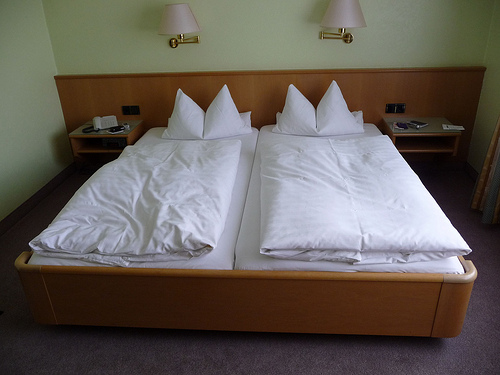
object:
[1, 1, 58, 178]
wall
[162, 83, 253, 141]
pillow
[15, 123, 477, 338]
bed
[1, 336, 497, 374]
carpet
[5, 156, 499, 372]
floor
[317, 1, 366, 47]
lights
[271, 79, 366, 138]
pillows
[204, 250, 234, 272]
mattresses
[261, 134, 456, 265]
sheets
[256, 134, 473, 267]
blankets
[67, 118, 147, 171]
night stand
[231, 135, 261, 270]
line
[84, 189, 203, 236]
wrinkle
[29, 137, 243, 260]
blanket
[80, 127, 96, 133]
objects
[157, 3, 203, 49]
light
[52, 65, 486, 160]
headboard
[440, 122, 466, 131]
paper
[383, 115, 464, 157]
night stand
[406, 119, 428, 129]
book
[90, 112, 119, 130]
telephone